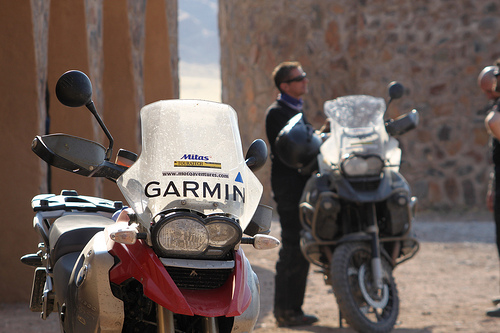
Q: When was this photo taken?
A: In the daytime.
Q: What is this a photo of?
A: Motorcycles in street.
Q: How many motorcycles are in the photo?
A: Two.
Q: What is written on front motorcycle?
A: Garmin.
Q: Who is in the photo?
A: Two men.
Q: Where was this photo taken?
A: On a street.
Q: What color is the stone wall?
A: Brown.